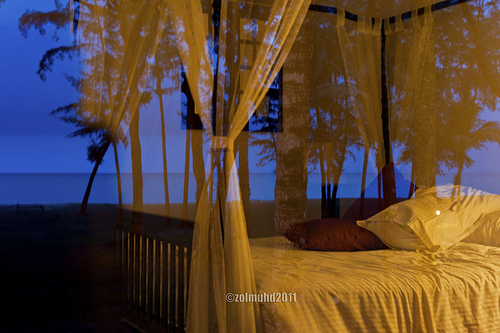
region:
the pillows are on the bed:
[291, 183, 473, 252]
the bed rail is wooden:
[94, 199, 193, 297]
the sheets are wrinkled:
[263, 250, 475, 312]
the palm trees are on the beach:
[68, 92, 470, 176]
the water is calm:
[5, 173, 70, 197]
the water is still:
[9, 166, 78, 205]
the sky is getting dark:
[0, 60, 67, 164]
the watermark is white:
[220, 287, 301, 307]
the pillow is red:
[286, 210, 382, 259]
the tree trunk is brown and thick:
[275, 95, 310, 231]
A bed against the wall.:
[93, 173, 498, 331]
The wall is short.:
[0, 201, 422, 331]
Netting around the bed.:
[66, 1, 497, 331]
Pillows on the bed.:
[290, 177, 497, 269]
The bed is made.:
[243, 198, 495, 331]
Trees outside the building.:
[45, 5, 499, 176]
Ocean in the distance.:
[11, 170, 466, 200]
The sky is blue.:
[9, 8, 463, 176]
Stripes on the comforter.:
[268, 235, 499, 331]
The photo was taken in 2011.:
[267, 282, 309, 309]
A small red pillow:
[283, 212, 378, 249]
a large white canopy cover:
[161, 0, 306, 330]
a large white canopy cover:
[70, 0, 160, 135]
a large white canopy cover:
[330, 0, 437, 175]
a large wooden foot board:
[109, 201, 193, 331]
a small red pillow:
[346, 160, 415, 222]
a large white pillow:
[357, 183, 499, 251]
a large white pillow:
[466, 212, 499, 242]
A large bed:
[132, 233, 499, 332]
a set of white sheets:
[120, 233, 499, 332]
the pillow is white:
[356, 174, 496, 258]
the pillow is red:
[276, 201, 378, 256]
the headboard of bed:
[106, 199, 214, 319]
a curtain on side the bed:
[155, 5, 317, 327]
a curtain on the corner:
[343, 9, 438, 203]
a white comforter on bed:
[239, 223, 499, 331]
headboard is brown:
[103, 202, 195, 325]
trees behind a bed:
[12, 5, 495, 332]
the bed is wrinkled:
[226, 210, 498, 331]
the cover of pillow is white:
[343, 165, 498, 252]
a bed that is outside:
[100, 100, 475, 316]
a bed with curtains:
[101, 41, 479, 328]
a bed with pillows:
[160, 82, 469, 311]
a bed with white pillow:
[201, 91, 463, 268]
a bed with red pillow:
[230, 79, 414, 329]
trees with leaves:
[33, 7, 285, 266]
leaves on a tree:
[53, 33, 228, 198]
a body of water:
[14, 177, 94, 219]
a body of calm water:
[54, 168, 172, 226]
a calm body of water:
[33, 177, 195, 218]